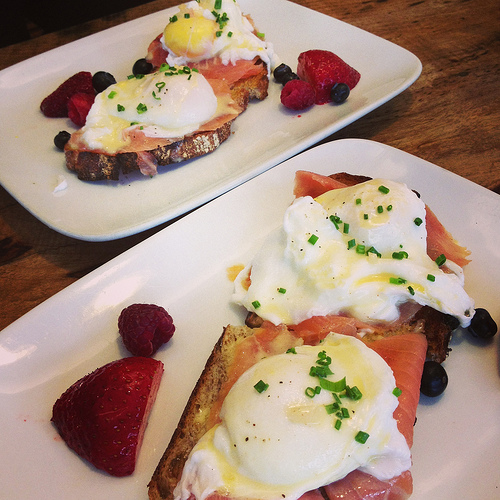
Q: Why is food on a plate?
A: To be eaten.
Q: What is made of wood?
A: The table.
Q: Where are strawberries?
A: On two plates.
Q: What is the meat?
A: Fish.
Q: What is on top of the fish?
A: Sour cream.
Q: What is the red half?
A: A strawberry.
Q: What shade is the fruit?
A: Red.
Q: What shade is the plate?
A: White.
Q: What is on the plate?
A: Food.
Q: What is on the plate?
A: Delicious food.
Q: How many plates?
A: Two.